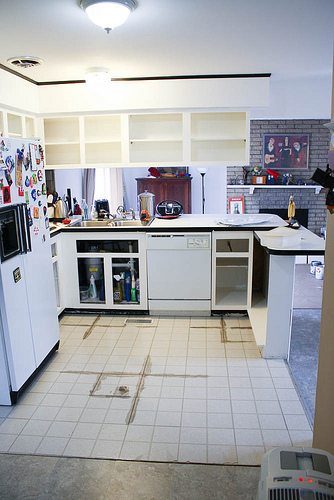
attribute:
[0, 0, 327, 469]
kitchen — white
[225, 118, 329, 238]
brick fireplace — gray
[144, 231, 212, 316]
dishwasher — white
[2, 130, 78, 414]
fridge — white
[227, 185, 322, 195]
mantel — white, wood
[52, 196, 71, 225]
kettle — black, silver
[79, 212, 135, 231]
sink — garbage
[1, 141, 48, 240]
magnets — many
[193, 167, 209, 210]
lamp — floor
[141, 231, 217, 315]
dishwasher — white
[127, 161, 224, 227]
cabinet — brown, wooden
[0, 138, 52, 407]
refrigerator — white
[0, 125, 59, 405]
refrigerator — white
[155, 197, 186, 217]
radio — portable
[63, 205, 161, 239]
sink — steel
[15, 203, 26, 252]
handle — black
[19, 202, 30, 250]
handle — black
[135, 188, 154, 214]
pot — silver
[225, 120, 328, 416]
room — living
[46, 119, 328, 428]
room — living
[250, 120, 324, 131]
wall — brick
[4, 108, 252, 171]
cabinet — empty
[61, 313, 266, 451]
tiles — beige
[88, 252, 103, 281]
disposal — silver